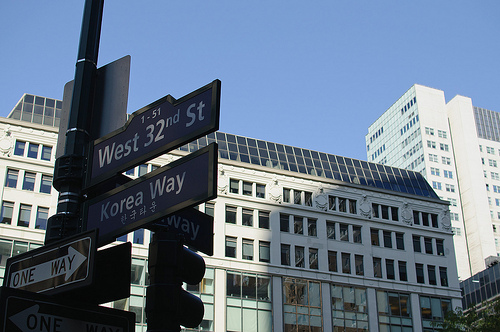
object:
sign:
[0, 285, 135, 332]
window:
[438, 266, 450, 287]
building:
[0, 91, 465, 332]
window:
[226, 268, 242, 298]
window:
[398, 260, 407, 281]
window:
[431, 213, 439, 228]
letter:
[108, 201, 120, 217]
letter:
[165, 176, 175, 193]